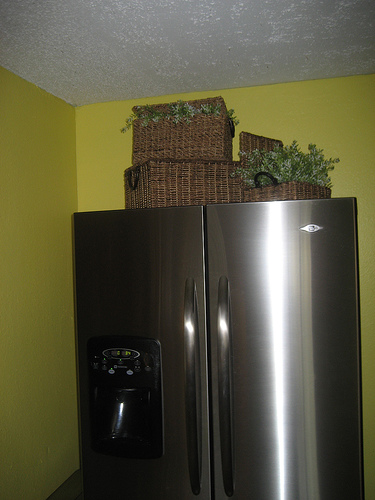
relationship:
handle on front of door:
[181, 277, 202, 496] [69, 195, 363, 498]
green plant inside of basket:
[233, 144, 342, 185] [235, 128, 331, 198]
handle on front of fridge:
[181, 277, 202, 496] [70, 197, 364, 498]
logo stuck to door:
[299, 215, 331, 231] [212, 189, 374, 497]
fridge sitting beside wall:
[70, 197, 364, 498] [0, 65, 79, 498]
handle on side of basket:
[122, 162, 145, 192] [125, 160, 245, 205]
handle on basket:
[216, 274, 236, 498] [124, 157, 241, 207]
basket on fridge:
[123, 156, 242, 209] [70, 197, 364, 498]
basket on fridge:
[239, 132, 331, 202] [70, 197, 364, 498]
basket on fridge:
[131, 95, 235, 164] [70, 197, 364, 498]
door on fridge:
[204, 197, 360, 499] [85, 181, 362, 343]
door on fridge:
[69, 206, 209, 497] [85, 181, 362, 343]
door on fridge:
[204, 197, 360, 499] [73, 197, 367, 499]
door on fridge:
[69, 206, 209, 497] [73, 197, 367, 499]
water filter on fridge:
[86, 339, 166, 423] [70, 197, 364, 498]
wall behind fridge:
[337, 79, 360, 120] [73, 197, 367, 499]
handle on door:
[216, 274, 236, 498] [204, 197, 360, 499]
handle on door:
[181, 277, 202, 498] [69, 206, 209, 497]